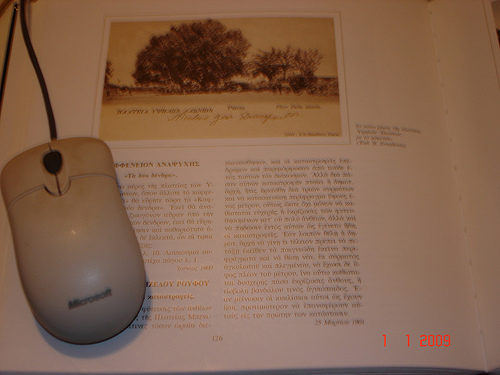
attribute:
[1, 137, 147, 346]
mouse — plastic, on the paper, microsoft, grey, white, old, wired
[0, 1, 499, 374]
book — open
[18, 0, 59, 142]
wire — black, dark grey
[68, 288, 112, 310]
word — microsoft, dark grey, name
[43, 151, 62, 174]
scroll wheel — black, small, dark grey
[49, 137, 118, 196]
button — right-click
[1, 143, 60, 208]
button — left-click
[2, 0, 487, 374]
page — 126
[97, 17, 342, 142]
picture — black, white, trees in a field, drawing, illustration, sepia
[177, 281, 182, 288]
letter — black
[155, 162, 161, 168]
letter — black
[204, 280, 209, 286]
letter — black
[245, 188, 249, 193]
letter — black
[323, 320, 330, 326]
letter — black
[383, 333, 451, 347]
date — 1 1 2009, red, orange, 1/1/2009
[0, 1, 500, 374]
picture — indoors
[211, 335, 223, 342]
page number — 126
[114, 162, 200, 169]
title — bold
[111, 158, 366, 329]
text — formatted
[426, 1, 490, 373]
binding — threaded, thread